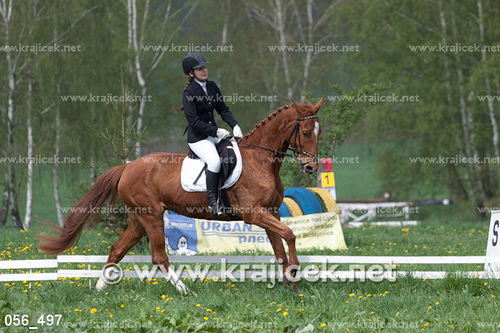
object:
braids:
[173, 70, 194, 111]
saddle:
[178, 138, 249, 193]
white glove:
[217, 128, 229, 140]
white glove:
[232, 125, 244, 138]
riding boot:
[205, 168, 224, 212]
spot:
[307, 109, 320, 140]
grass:
[212, 293, 254, 323]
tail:
[31, 166, 125, 261]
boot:
[203, 153, 228, 212]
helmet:
[182, 54, 209, 76]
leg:
[261, 214, 286, 278]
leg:
[261, 210, 290, 287]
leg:
[137, 213, 189, 293]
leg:
[95, 210, 143, 291]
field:
[18, 207, 497, 327]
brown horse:
[36, 95, 324, 297]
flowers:
[75, 300, 106, 320]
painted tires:
[273, 179, 350, 245]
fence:
[0, 253, 497, 284]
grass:
[445, 304, 494, 332]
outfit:
[181, 75, 247, 198]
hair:
[182, 67, 194, 93]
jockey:
[177, 49, 247, 218]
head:
[288, 93, 328, 176]